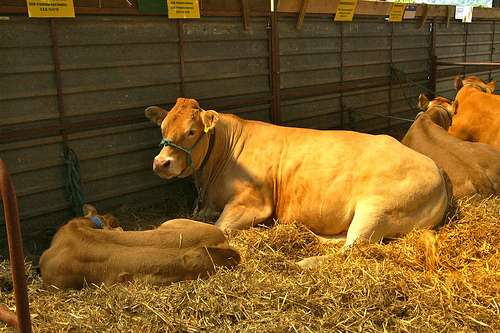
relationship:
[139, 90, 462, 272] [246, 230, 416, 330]
cow sitting on hay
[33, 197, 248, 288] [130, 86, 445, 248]
cow sitting on cow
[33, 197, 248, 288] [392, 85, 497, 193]
cow sitting on cow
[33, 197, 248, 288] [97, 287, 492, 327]
cow sitting on hay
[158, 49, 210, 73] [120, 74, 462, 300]
sign above cow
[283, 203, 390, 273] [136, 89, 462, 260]
leg of cow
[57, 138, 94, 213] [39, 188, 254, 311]
rope holding cow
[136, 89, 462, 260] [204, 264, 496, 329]
cow lying on straw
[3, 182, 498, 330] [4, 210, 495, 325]
straw on ground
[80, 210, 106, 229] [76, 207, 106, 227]
collar on neck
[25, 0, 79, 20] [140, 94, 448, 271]
sign above cows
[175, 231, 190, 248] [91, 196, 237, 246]
straw on back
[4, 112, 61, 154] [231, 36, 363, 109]
rust covered fencing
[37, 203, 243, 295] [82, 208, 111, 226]
cow wearing collar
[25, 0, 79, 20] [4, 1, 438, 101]
sign along wall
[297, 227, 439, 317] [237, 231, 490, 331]
pile of hay